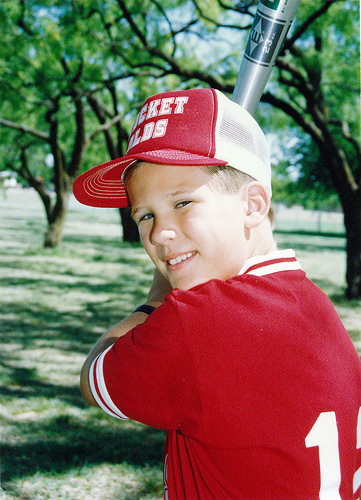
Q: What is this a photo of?
A: A uniformed baseball player.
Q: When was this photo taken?
A: During the daytime.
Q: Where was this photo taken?
A: In the park.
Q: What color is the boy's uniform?
A: Red and white.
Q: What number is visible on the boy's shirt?
A: One.